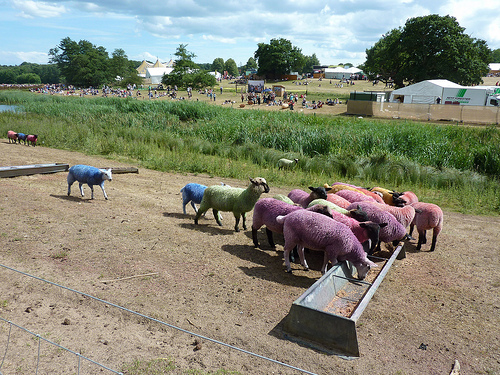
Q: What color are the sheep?
A: Pink and blue.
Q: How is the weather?
A: Cloudy.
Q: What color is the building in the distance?
A: White.